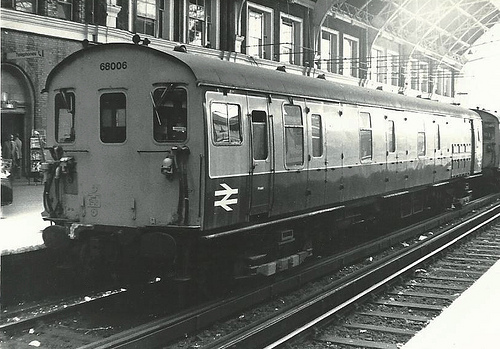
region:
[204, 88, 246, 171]
Smal window on train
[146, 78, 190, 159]
Smal window on train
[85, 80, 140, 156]
Smal window on train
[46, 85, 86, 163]
Smal window on train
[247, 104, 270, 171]
Smal window on train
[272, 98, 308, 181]
Smal window on train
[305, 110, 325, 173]
Smal window on train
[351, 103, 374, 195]
Smal window on train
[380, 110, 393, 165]
Smal window on train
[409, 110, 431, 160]
Smal window on train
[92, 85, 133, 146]
the window of a train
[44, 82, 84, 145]
the window of a train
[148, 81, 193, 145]
the window of a train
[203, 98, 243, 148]
the window of a train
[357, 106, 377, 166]
the window of a train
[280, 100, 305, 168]
the window of a train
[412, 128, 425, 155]
the window of a train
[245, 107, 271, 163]
the window of a train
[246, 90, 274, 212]
the door of a train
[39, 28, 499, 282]
train on tracks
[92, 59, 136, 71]
number on the back of the train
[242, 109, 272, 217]
door on the side of the train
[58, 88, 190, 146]
three windows on the back of the train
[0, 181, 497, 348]
train tracks on the ground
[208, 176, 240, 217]
white symbol on the back side corner of the train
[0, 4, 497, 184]
train station structure next to the train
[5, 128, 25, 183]
people at the train station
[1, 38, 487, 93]
cable wires for the train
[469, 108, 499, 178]
area where two trains attach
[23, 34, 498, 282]
a train on train tracks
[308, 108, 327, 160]
the window of a train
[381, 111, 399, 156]
the window of a train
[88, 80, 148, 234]
the door of a train car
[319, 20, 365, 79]
the windows of a building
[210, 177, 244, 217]
white symbol on train car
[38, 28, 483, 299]
train car sitting on railroad tracks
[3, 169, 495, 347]
railroad tracks on ground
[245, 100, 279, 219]
door to railroad car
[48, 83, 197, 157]
back windows of rail car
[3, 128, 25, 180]
people standing in archway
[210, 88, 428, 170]
side windows of train car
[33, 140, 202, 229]
pipes on back of train car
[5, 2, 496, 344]
train sitting in a train station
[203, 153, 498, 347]
on empty set of railroad tracks